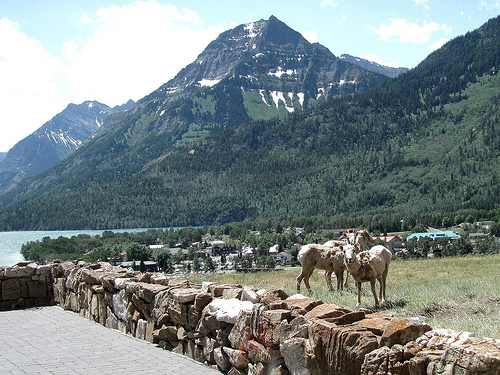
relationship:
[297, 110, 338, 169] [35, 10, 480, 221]
hill in background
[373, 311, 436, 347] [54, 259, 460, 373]
stone on wall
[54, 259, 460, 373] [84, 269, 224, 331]
wall made of rocks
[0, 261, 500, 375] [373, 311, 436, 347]
wall made of stone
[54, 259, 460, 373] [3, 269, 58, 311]
wall made of rocks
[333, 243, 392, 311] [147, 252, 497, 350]
animal standing in field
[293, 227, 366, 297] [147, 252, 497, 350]
animal standing in field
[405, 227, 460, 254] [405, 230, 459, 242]
building has roof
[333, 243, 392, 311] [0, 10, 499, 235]
animal standing together with mountain backdrop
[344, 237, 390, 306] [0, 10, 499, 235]
animal standing together with mountain backdrop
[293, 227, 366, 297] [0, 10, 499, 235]
animal standing together with mountain backdrop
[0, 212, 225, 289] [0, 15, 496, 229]
water at foot of a mountain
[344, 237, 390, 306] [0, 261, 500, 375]
animal standing near wall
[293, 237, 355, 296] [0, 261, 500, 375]
animal standing near wall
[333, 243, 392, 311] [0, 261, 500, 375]
animal standing near wall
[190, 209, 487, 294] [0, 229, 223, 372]
village standing near water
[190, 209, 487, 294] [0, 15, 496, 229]
village standing near mountain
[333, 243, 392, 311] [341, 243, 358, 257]
animal has eyes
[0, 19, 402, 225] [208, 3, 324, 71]
mountain has peak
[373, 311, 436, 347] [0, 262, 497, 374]
stone used on wall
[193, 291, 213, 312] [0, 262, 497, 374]
stone used on wall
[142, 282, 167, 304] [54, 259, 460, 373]
stone used on wall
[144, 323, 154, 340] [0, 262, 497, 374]
stone used on wall